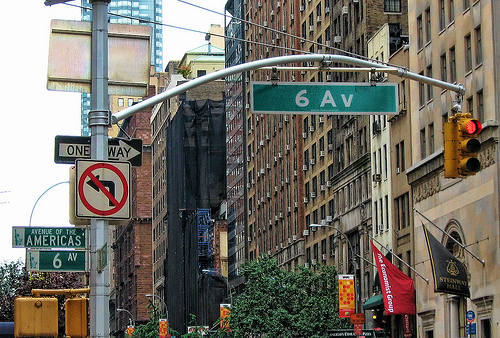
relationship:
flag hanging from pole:
[369, 239, 415, 316] [365, 225, 432, 286]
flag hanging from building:
[369, 239, 415, 316] [412, 0, 499, 337]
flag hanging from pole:
[361, 234, 418, 319] [364, 226, 435, 282]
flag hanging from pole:
[369, 239, 415, 316] [364, 231, 429, 282]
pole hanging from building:
[364, 231, 429, 282] [357, 0, 494, 336]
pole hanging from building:
[364, 231, 429, 282] [384, 0, 489, 323]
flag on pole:
[369, 239, 415, 316] [365, 223, 432, 292]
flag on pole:
[369, 239, 415, 316] [363, 230, 429, 283]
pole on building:
[363, 230, 429, 283] [404, 2, 497, 337]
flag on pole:
[369, 239, 415, 316] [372, 230, 432, 293]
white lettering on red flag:
[376, 252, 396, 311] [370, 244, 415, 316]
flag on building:
[369, 239, 415, 316] [381, 31, 489, 320]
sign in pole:
[72, 153, 136, 220] [83, 3, 113, 336]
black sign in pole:
[52, 135, 143, 167] [83, 3, 113, 336]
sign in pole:
[23, 247, 86, 269] [110, 49, 467, 130]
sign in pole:
[12, 223, 87, 247] [110, 49, 467, 130]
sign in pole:
[250, 81, 400, 115] [83, 3, 113, 336]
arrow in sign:
[60, 136, 144, 166] [55, 130, 153, 164]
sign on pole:
[249, 81, 399, 116] [111, 50, 466, 123]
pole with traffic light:
[111, 50, 466, 123] [440, 110, 479, 179]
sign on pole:
[72, 158, 132, 220] [79, 7, 116, 332]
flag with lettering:
[409, 202, 474, 298] [438, 275, 469, 292]